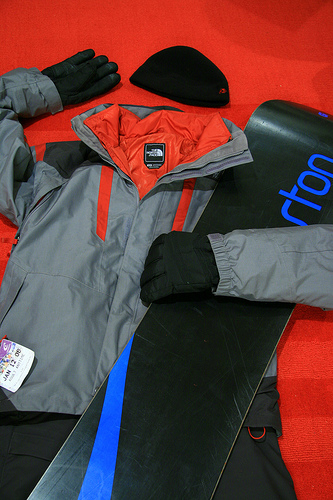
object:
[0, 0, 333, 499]
surface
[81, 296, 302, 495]
skipants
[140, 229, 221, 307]
glove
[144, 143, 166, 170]
tag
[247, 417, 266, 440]
tag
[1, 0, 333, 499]
material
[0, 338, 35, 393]
white tag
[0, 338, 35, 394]
ticket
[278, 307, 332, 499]
blanket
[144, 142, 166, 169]
black label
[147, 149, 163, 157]
white logo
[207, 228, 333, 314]
coat sleeve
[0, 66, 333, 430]
grey jacket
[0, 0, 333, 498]
background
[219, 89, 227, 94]
orange logo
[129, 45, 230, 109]
black cap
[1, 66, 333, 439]
coat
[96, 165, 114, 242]
orange lining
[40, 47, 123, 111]
gloves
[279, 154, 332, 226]
logo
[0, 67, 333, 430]
jacket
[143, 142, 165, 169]
logo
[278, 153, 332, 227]
blue lettering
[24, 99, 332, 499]
black snowboard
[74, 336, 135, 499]
strip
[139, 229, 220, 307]
hand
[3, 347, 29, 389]
writing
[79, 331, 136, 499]
design